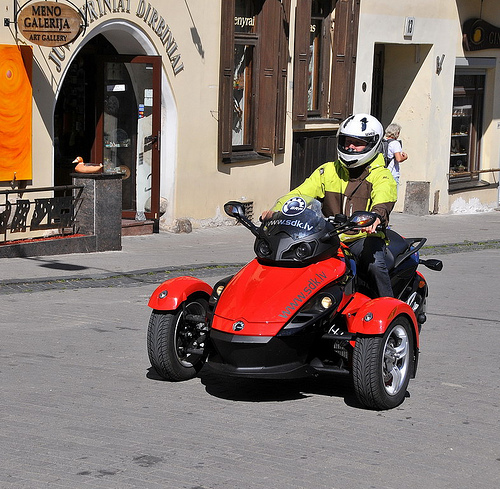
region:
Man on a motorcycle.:
[139, 110, 444, 410]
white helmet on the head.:
[331, 110, 388, 174]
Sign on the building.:
[8, 3, 93, 49]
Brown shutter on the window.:
[256, 0, 291, 160]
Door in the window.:
[371, 45, 432, 211]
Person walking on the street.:
[384, 123, 407, 186]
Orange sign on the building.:
[0, 43, 36, 183]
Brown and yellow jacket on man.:
[258, 105, 401, 239]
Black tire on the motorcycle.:
[345, 318, 423, 412]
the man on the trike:
[143, 110, 447, 410]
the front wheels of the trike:
[150, 299, 416, 415]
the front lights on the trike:
[255, 233, 316, 260]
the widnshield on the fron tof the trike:
[268, 196, 322, 228]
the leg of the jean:
[348, 237, 395, 301]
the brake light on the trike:
[419, 255, 445, 278]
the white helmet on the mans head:
[335, 114, 390, 166]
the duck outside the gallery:
[70, 151, 102, 175]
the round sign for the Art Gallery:
[15, 0, 82, 51]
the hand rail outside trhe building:
[2, 183, 79, 240]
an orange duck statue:
[69, 154, 104, 173]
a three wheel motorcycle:
[148, 199, 442, 409]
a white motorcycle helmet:
[333, 114, 385, 169]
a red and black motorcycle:
[143, 211, 429, 397]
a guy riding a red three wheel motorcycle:
[146, 114, 446, 406]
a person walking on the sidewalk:
[385, 122, 410, 189]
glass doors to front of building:
[60, 54, 157, 224]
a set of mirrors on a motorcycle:
[218, 200, 376, 225]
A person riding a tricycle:
[143, 114, 442, 409]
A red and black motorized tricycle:
[145, 201, 445, 411]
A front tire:
[352, 313, 414, 410]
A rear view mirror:
[220, 201, 259, 236]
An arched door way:
[52, 18, 174, 231]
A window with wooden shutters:
[218, 1, 289, 156]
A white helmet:
[333, 111, 385, 170]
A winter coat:
[272, 150, 395, 237]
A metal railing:
[1, 184, 84, 239]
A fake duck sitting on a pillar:
[70, 156, 104, 173]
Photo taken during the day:
[9, 13, 489, 474]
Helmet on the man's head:
[326, 113, 383, 176]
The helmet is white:
[334, 103, 389, 169]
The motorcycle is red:
[129, 196, 438, 391]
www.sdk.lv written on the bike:
[273, 264, 343, 325]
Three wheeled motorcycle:
[158, 202, 448, 397]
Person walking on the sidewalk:
[384, 121, 411, 204]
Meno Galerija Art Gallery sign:
[18, 0, 94, 49]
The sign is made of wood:
[18, 2, 95, 46]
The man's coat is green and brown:
[261, 154, 396, 246]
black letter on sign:
[23, 12, 33, 29]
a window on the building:
[221, 43, 258, 133]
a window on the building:
[315, 21, 330, 89]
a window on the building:
[448, 78, 480, 191]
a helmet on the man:
[326, 105, 387, 178]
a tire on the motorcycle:
[353, 308, 415, 396]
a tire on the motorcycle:
[148, 306, 215, 379]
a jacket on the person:
[289, 144, 398, 252]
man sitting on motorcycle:
[258, 100, 408, 273]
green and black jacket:
[274, 148, 398, 238]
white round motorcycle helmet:
[332, 105, 390, 169]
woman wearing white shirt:
[380, 118, 412, 203]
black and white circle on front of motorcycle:
[277, 199, 312, 229]